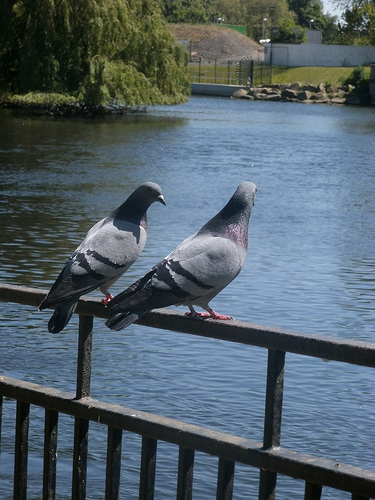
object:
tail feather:
[46, 300, 76, 334]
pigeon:
[104, 180, 257, 331]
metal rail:
[0, 281, 375, 500]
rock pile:
[226, 78, 354, 107]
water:
[4, 93, 372, 497]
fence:
[156, 59, 283, 91]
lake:
[1, 97, 374, 495]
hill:
[184, 60, 373, 87]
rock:
[313, 91, 328, 99]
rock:
[296, 90, 311, 98]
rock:
[281, 88, 298, 98]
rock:
[233, 88, 248, 99]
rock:
[289, 81, 303, 91]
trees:
[0, 0, 194, 108]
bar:
[262, 347, 285, 447]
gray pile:
[253, 74, 356, 104]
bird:
[38, 182, 166, 337]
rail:
[0, 275, 375, 500]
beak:
[158, 195, 168, 210]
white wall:
[261, 42, 373, 66]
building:
[263, 34, 373, 67]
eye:
[143, 182, 152, 203]